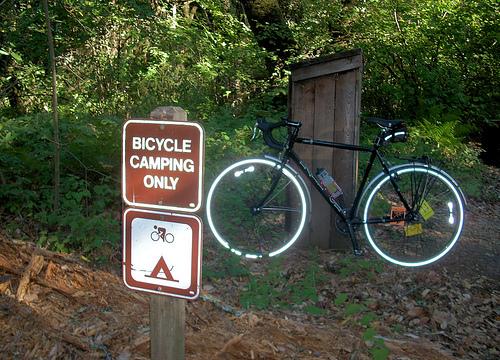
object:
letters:
[129, 134, 195, 191]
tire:
[357, 163, 468, 269]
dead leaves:
[350, 272, 498, 345]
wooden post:
[147, 106, 187, 359]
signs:
[121, 119, 202, 213]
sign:
[123, 208, 202, 299]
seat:
[364, 116, 409, 143]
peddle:
[344, 237, 384, 264]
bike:
[150, 225, 174, 242]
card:
[405, 222, 423, 237]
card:
[416, 200, 434, 221]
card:
[390, 205, 404, 226]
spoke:
[411, 239, 427, 259]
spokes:
[206, 158, 308, 258]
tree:
[41, 0, 64, 233]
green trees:
[258, 114, 297, 155]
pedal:
[347, 242, 366, 261]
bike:
[206, 116, 467, 269]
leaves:
[404, 297, 486, 351]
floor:
[280, 286, 495, 355]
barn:
[280, 47, 366, 254]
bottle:
[313, 165, 344, 200]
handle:
[255, 116, 300, 150]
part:
[356, 216, 466, 268]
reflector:
[231, 165, 255, 178]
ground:
[1, 156, 500, 357]